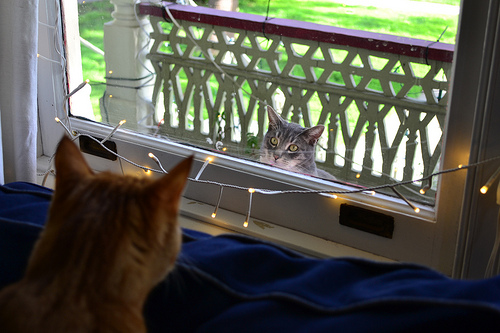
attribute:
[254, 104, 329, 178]
cat — gray, brown, striped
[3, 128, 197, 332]
cat — orange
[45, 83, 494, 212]
lights — on, string, small, holiday lights, white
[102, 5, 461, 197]
railing — white, wooden, ornate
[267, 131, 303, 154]
eyes — open, yellow, big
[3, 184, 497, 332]
blanket — blue, deep blue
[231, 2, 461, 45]
grass — green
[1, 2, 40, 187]
curtain — hanging, white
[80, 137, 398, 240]
handles — dark, brass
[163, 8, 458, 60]
border — dark, wood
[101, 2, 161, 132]
pillar — carved, white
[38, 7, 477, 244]
frame — white